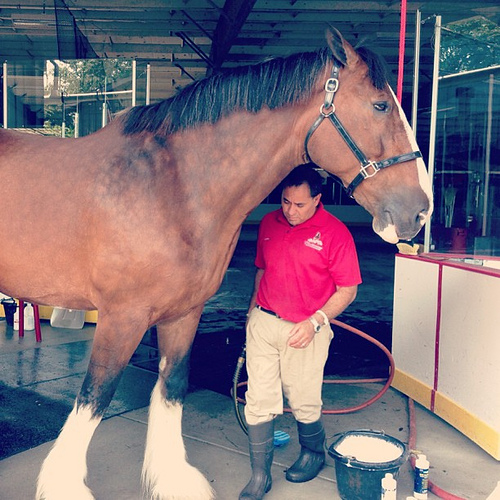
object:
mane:
[114, 45, 387, 140]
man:
[237, 168, 362, 499]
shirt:
[253, 199, 363, 325]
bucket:
[320, 423, 410, 498]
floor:
[0, 224, 499, 499]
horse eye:
[372, 102, 387, 112]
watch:
[308, 316, 322, 334]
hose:
[229, 317, 395, 415]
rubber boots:
[237, 417, 276, 498]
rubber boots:
[284, 415, 328, 483]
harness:
[304, 61, 421, 201]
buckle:
[319, 77, 340, 118]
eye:
[372, 101, 389, 112]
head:
[305, 24, 433, 245]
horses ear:
[324, 22, 359, 68]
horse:
[0, 22, 435, 498]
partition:
[389, 1, 499, 459]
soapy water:
[336, 432, 403, 462]